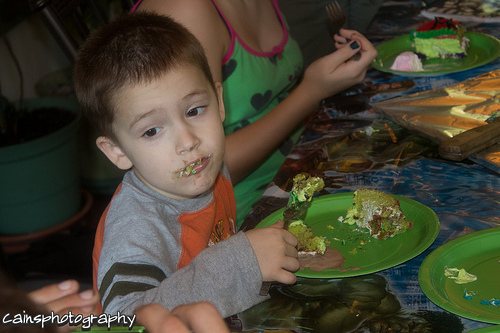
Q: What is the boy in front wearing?
A: Grey and orange shirt.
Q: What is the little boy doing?
A: Eating cake.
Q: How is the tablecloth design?
A: Movie theme prints.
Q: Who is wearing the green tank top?
A: Woman next to front boy.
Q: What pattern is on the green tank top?
A: Hearts.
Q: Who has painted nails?
A: Woman in green tank top.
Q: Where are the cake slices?
A: On round green plates.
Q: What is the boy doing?
A: Eating.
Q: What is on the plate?
A: A piece of cake.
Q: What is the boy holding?
A: Fork.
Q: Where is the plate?
A: On a table.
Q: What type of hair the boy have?
A: Short brown hair.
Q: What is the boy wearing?
A: Grey and orange color t shirt.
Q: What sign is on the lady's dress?
A: Love sign.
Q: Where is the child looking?
A: Looking Photographer.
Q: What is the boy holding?
A: A fork.